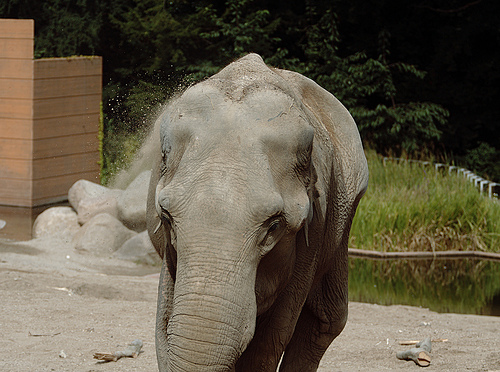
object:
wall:
[2, 20, 35, 207]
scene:
[0, 0, 500, 371]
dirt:
[0, 242, 500, 371]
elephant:
[126, 53, 373, 372]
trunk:
[167, 221, 259, 372]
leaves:
[397, 124, 407, 134]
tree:
[463, 142, 500, 183]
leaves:
[440, 121, 447, 126]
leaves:
[444, 111, 451, 117]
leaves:
[198, 32, 208, 35]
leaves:
[88, 29, 98, 35]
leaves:
[262, 9, 272, 18]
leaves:
[41, 47, 49, 54]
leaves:
[143, 29, 152, 37]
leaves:
[143, 30, 151, 38]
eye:
[255, 217, 284, 247]